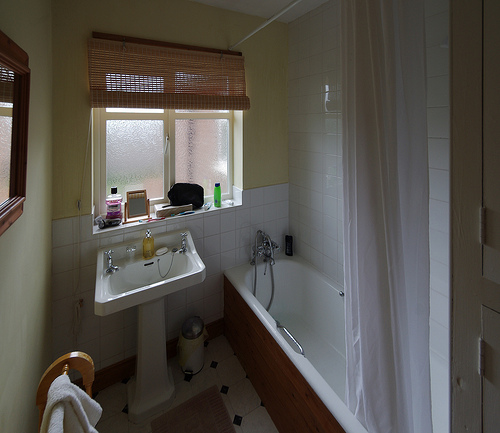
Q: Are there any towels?
A: Yes, there is a towel.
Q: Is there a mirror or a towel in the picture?
A: Yes, there is a towel.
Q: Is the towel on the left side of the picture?
A: Yes, the towel is on the left of the image.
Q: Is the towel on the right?
A: No, the towel is on the left of the image.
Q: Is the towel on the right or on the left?
A: The towel is on the left of the image.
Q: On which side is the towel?
A: The towel is on the left of the image.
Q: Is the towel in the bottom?
A: Yes, the towel is in the bottom of the image.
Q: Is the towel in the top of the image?
A: No, the towel is in the bottom of the image.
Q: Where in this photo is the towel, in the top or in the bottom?
A: The towel is in the bottom of the image.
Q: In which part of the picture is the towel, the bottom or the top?
A: The towel is in the bottom of the image.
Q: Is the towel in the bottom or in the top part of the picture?
A: The towel is in the bottom of the image.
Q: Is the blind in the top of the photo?
A: Yes, the blind is in the top of the image.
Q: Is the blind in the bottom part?
A: No, the blind is in the top of the image.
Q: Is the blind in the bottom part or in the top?
A: The blind is in the top of the image.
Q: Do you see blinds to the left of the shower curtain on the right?
A: Yes, there is a blind to the left of the shower curtain.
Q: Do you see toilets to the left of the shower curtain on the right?
A: No, there is a blind to the left of the shower curtain.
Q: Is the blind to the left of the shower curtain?
A: Yes, the blind is to the left of the shower curtain.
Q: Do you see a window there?
A: Yes, there is a window.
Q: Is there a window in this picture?
A: Yes, there is a window.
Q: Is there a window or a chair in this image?
A: Yes, there is a window.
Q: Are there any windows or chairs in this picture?
A: Yes, there is a window.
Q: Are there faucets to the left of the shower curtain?
A: Yes, there is a faucet to the left of the shower curtain.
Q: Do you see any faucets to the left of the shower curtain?
A: Yes, there is a faucet to the left of the shower curtain.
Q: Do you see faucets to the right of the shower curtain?
A: No, the faucet is to the left of the shower curtain.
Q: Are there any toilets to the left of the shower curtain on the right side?
A: No, there is a faucet to the left of the shower curtain.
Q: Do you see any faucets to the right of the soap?
A: Yes, there is a faucet to the right of the soap.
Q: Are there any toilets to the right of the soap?
A: No, there is a faucet to the right of the soap.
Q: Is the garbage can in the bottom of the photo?
A: Yes, the garbage can is in the bottom of the image.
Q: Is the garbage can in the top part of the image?
A: No, the garbage can is in the bottom of the image.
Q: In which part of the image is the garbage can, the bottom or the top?
A: The garbage can is in the bottom of the image.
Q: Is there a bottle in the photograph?
A: Yes, there is a bottle.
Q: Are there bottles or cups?
A: Yes, there is a bottle.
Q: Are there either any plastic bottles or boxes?
A: Yes, there is a plastic bottle.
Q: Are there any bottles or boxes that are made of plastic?
A: Yes, the bottle is made of plastic.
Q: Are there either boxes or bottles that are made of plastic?
A: Yes, the bottle is made of plastic.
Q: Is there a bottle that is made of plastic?
A: Yes, there is a bottle that is made of plastic.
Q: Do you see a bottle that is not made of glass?
A: Yes, there is a bottle that is made of plastic.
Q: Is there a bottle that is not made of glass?
A: Yes, there is a bottle that is made of plastic.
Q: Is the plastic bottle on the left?
A: Yes, the bottle is on the left of the image.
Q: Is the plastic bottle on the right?
A: No, the bottle is on the left of the image.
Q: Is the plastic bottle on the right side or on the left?
A: The bottle is on the left of the image.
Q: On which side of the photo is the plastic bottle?
A: The bottle is on the left of the image.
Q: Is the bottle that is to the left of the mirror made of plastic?
A: Yes, the bottle is made of plastic.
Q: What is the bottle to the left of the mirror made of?
A: The bottle is made of plastic.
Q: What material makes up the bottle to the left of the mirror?
A: The bottle is made of plastic.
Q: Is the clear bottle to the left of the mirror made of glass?
A: No, the bottle is made of plastic.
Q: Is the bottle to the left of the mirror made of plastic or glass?
A: The bottle is made of plastic.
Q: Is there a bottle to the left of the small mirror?
A: Yes, there is a bottle to the left of the mirror.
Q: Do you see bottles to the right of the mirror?
A: No, the bottle is to the left of the mirror.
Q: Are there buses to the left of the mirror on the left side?
A: No, there is a bottle to the left of the mirror.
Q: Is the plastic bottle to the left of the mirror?
A: Yes, the bottle is to the left of the mirror.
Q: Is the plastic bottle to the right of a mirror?
A: No, the bottle is to the left of a mirror.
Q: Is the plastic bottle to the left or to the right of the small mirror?
A: The bottle is to the left of the mirror.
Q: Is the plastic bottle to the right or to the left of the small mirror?
A: The bottle is to the left of the mirror.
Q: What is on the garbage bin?
A: The lid is on the garbage bin.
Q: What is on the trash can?
A: The lid is on the garbage bin.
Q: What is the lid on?
A: The lid is on the garbage bin.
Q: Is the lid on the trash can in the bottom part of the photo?
A: Yes, the lid is on the trash bin.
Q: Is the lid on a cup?
A: No, the lid is on the trash bin.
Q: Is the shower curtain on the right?
A: Yes, the shower curtain is on the right of the image.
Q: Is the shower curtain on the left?
A: No, the shower curtain is on the right of the image.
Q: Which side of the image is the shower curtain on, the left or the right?
A: The shower curtain is on the right of the image.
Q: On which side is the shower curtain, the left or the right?
A: The shower curtain is on the right of the image.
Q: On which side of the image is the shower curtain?
A: The shower curtain is on the right of the image.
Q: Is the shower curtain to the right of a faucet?
A: Yes, the shower curtain is to the right of a faucet.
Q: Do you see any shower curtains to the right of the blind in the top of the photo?
A: Yes, there is a shower curtain to the right of the blind.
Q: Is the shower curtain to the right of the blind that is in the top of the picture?
A: Yes, the shower curtain is to the right of the blind.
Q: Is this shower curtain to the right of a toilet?
A: No, the shower curtain is to the right of the blind.